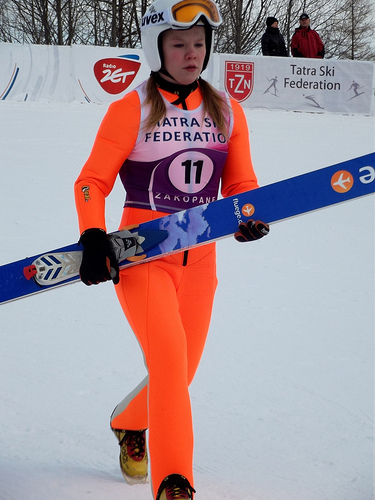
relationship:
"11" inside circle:
[179, 158, 206, 187] [167, 148, 216, 195]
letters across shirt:
[146, 110, 224, 143] [114, 83, 238, 212]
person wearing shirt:
[70, 3, 286, 499] [114, 83, 238, 212]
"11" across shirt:
[179, 158, 206, 187] [114, 83, 238, 212]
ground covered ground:
[0, 173, 372, 496] [12, 122, 337, 496]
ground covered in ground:
[9, 307, 352, 498] [0, 173, 372, 496]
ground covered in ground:
[0, 173, 372, 496] [8, 104, 362, 477]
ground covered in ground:
[0, 173, 372, 496] [29, 314, 346, 496]